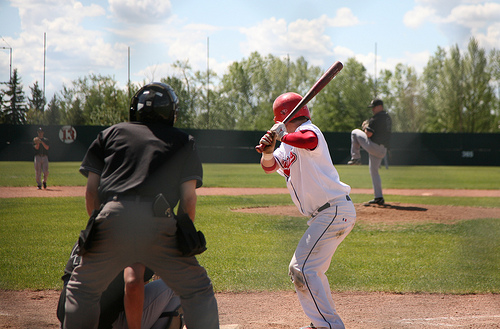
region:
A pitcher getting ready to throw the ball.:
[347, 93, 393, 208]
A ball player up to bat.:
[256, 83, 350, 326]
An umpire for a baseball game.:
[63, 81, 233, 324]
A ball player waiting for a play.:
[29, 125, 55, 188]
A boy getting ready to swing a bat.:
[251, 54, 359, 327]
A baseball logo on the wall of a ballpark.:
[54, 122, 79, 146]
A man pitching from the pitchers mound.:
[347, 91, 394, 213]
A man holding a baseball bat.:
[254, 59, 345, 325]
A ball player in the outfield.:
[31, 121, 53, 188]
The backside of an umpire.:
[61, 79, 211, 325]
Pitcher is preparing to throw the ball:
[348, 89, 393, 214]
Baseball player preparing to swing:
[250, 52, 377, 327]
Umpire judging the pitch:
[65, 72, 224, 325]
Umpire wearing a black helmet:
[125, 78, 181, 121]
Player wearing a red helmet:
[267, 88, 309, 125]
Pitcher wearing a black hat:
[367, 91, 385, 108]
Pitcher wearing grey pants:
[349, 128, 391, 203]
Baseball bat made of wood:
[256, 53, 342, 154]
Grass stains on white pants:
[286, 263, 313, 293]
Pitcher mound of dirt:
[248, 193, 496, 222]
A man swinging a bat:
[327, 70, 332, 76]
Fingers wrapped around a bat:
[265, 137, 271, 142]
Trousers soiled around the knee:
[293, 274, 299, 280]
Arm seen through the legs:
[127, 271, 138, 319]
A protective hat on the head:
[276, 101, 291, 110]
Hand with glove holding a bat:
[274, 126, 283, 132]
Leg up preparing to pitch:
[352, 136, 357, 156]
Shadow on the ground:
[409, 206, 418, 209]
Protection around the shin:
[175, 317, 178, 327]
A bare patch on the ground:
[362, 301, 407, 314]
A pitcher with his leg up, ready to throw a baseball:
[347, 97, 392, 206]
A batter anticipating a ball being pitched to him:
[257, 90, 357, 327]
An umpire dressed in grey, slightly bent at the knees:
[61, 78, 221, 327]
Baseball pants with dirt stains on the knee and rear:
[288, 193, 359, 328]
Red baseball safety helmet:
[270, 90, 310, 124]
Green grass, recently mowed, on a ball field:
[1, 159, 498, 294]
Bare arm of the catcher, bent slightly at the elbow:
[122, 263, 148, 327]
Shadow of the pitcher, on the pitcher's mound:
[385, 200, 427, 211]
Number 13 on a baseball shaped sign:
[56, 121, 78, 146]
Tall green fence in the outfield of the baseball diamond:
[2, 123, 499, 167]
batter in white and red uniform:
[252, 57, 354, 321]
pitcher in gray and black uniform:
[344, 96, 399, 216]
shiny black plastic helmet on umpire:
[124, 81, 180, 134]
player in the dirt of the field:
[25, 124, 63, 206]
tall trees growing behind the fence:
[181, 52, 258, 137]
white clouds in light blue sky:
[113, 10, 213, 52]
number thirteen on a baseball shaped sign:
[53, 111, 78, 152]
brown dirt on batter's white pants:
[286, 222, 355, 312]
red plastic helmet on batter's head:
[263, 86, 333, 136]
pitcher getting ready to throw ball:
[343, 97, 400, 225]